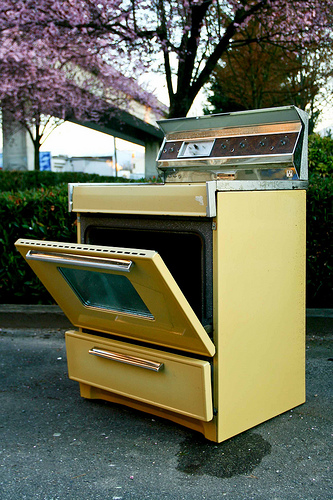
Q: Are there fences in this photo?
A: No, there are no fences.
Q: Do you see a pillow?
A: No, there are no pillows.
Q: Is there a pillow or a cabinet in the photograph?
A: No, there are no pillows or cabinets.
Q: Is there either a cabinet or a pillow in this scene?
A: No, there are no pillows or cabinets.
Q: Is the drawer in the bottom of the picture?
A: Yes, the drawer is in the bottom of the image.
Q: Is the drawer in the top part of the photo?
A: No, the drawer is in the bottom of the image.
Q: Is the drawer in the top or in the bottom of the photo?
A: The drawer is in the bottom of the image.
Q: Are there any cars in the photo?
A: No, there are no cars.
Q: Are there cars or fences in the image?
A: No, there are no cars or fences.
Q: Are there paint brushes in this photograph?
A: No, there are no paint brushes.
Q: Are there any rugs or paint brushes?
A: No, there are no paint brushes or rugs.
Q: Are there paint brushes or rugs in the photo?
A: No, there are no paint brushes or rugs.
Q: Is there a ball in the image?
A: No, there are no balls.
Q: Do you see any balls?
A: No, there are no balls.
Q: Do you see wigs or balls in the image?
A: No, there are no balls or wigs.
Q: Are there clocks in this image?
A: Yes, there is a clock.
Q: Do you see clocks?
A: Yes, there is a clock.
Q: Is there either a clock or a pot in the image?
A: Yes, there is a clock.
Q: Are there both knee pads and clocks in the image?
A: No, there is a clock but no knee pads.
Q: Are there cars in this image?
A: No, there are no cars.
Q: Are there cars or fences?
A: No, there are no cars or fences.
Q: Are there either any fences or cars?
A: No, there are no cars or fences.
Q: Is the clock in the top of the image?
A: Yes, the clock is in the top of the image.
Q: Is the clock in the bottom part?
A: No, the clock is in the top of the image.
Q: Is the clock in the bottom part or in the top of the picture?
A: The clock is in the top of the image.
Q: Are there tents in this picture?
A: No, there are no tents.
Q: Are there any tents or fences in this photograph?
A: No, there are no tents or fences.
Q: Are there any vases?
A: No, there are no vases.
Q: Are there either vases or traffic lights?
A: No, there are no vases or traffic lights.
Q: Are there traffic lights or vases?
A: No, there are no vases or traffic lights.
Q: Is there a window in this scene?
A: Yes, there is a window.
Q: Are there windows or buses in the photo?
A: Yes, there is a window.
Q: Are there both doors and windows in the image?
A: Yes, there are both a window and a door.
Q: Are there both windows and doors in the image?
A: Yes, there are both a window and a door.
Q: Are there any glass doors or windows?
A: Yes, there is a glass window.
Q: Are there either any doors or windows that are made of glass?
A: Yes, the window is made of glass.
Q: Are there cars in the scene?
A: No, there are no cars.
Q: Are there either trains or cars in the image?
A: No, there are no cars or trains.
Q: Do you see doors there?
A: Yes, there is a door.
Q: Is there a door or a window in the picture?
A: Yes, there is a door.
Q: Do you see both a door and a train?
A: No, there is a door but no trains.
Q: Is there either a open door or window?
A: Yes, there is an open door.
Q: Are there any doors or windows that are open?
A: Yes, the door is open.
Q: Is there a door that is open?
A: Yes, there is an open door.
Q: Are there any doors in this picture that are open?
A: Yes, there is a door that is open.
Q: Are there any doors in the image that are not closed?
A: Yes, there is a open door.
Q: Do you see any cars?
A: No, there are no cars.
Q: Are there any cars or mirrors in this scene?
A: No, there are no cars or mirrors.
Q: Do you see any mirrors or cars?
A: No, there are no cars or mirrors.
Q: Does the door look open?
A: Yes, the door is open.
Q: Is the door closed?
A: No, the door is open.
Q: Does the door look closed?
A: No, the door is open.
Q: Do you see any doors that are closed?
A: No, there is a door but it is open.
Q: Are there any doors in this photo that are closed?
A: No, there is a door but it is open.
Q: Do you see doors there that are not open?
A: No, there is a door but it is open.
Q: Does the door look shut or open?
A: The door is open.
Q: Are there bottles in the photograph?
A: No, there are no bottles.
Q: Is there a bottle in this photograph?
A: No, there are no bottles.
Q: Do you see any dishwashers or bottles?
A: No, there are no bottles or dishwashers.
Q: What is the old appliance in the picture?
A: The appliance is a stove.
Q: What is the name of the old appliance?
A: The appliance is a stove.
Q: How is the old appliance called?
A: The appliance is a stove.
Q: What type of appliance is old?
A: The appliance is a stove.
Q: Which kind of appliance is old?
A: The appliance is a stove.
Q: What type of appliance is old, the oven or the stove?
A: The stove is old.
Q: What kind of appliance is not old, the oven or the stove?
A: The oven is not old.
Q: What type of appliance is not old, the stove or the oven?
A: The oven is not old.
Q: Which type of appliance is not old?
A: The appliance is an oven.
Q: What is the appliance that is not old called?
A: The appliance is an oven.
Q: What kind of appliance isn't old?
A: The appliance is an oven.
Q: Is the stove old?
A: Yes, the stove is old.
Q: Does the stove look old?
A: Yes, the stove is old.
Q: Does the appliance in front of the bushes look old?
A: Yes, the stove is old.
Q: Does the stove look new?
A: No, the stove is old.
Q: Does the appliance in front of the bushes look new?
A: No, the stove is old.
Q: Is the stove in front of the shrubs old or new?
A: The stove is old.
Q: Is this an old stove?
A: Yes, this is an old stove.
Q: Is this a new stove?
A: No, this is an old stove.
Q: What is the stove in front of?
A: The stove is in front of the shrubs.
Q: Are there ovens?
A: Yes, there is an oven.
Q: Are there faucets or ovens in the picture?
A: Yes, there is an oven.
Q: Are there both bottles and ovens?
A: No, there is an oven but no bottles.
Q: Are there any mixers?
A: No, there are no mixers.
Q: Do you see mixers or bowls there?
A: No, there are no mixers or bowls.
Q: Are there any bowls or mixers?
A: No, there are no mixers or bowls.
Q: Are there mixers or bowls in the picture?
A: No, there are no mixers or bowls.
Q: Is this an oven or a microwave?
A: This is an oven.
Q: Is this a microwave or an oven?
A: This is an oven.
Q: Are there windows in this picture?
A: Yes, there is a window.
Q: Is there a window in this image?
A: Yes, there is a window.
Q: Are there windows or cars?
A: Yes, there is a window.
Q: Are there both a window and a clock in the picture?
A: Yes, there are both a window and a clock.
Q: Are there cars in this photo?
A: No, there are no cars.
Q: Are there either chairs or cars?
A: No, there are no cars or chairs.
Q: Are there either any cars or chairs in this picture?
A: No, there are no cars or chairs.